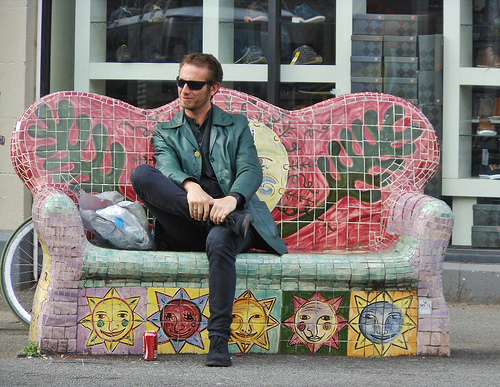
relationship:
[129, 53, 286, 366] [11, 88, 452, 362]
man sitting on bench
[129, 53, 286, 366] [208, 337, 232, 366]
man has shoe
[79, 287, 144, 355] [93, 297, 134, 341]
sun has face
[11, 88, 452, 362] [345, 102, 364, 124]
bench has tile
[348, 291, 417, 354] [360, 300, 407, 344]
sun has face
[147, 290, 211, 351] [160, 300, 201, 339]
sun has face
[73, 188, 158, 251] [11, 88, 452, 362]
bag laying on bench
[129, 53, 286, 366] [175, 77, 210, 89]
man wearing sunglasses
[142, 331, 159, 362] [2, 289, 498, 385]
can on top of ground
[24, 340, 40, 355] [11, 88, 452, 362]
weed next to bench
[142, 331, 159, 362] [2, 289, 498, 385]
can sitting on top of ground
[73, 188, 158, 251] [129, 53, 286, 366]
bag next to man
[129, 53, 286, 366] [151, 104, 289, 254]
man wearing jacket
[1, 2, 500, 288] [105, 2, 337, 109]
building has window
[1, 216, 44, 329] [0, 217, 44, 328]
bicycle has bicycle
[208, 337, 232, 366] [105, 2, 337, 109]
shoe behind window